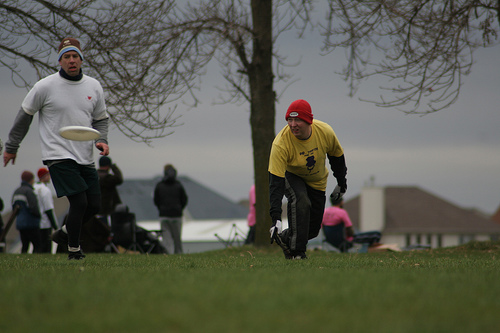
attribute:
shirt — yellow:
[267, 119, 343, 192]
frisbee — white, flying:
[58, 126, 102, 142]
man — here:
[6, 71, 110, 259]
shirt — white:
[22, 72, 109, 166]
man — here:
[270, 98, 347, 258]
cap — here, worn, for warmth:
[285, 100, 312, 125]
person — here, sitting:
[320, 196, 381, 251]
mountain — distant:
[238, 200, 292, 220]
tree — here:
[0, 1, 500, 246]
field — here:
[0, 241, 500, 332]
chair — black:
[110, 212, 167, 253]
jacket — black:
[152, 178, 188, 217]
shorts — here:
[44, 162, 102, 198]